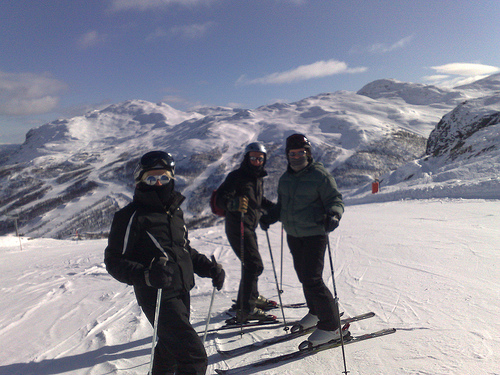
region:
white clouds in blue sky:
[22, 5, 67, 50]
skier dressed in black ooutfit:
[104, 146, 206, 348]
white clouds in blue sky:
[58, 15, 112, 47]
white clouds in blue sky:
[95, 43, 192, 84]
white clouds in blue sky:
[175, 21, 263, 82]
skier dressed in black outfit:
[205, 136, 275, 311]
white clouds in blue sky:
[251, 22, 329, 69]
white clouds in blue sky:
[345, 19, 412, 63]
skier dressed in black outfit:
[270, 132, 358, 317]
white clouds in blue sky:
[380, 29, 432, 66]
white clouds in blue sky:
[39, 43, 89, 81]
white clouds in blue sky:
[99, 23, 176, 55]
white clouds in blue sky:
[227, 17, 287, 42]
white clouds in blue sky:
[290, 45, 344, 85]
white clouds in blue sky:
[353, 28, 398, 53]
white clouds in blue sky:
[279, 38, 323, 66]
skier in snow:
[273, 128, 358, 335]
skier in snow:
[206, 144, 283, 301]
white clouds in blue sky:
[69, 49, 106, 66]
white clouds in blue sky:
[22, 63, 64, 101]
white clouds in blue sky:
[131, 30, 211, 94]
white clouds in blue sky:
[255, 40, 315, 89]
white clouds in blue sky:
[317, 7, 389, 45]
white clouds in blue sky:
[396, 20, 437, 48]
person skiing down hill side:
[270, 126, 360, 331]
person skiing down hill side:
[225, 130, 278, 312]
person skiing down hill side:
[112, 144, 221, 355]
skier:
[80, 148, 201, 366]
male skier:
[207, 138, 279, 305]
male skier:
[274, 132, 361, 370]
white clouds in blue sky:
[72, 59, 116, 93]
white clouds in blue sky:
[132, 11, 189, 75]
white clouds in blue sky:
[197, 11, 244, 69]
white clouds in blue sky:
[285, 35, 333, 76]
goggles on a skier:
[141, 171, 178, 184]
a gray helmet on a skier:
[243, 140, 271, 170]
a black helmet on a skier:
[284, 131, 312, 147]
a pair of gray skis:
[222, 307, 396, 373]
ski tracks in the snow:
[0, 288, 130, 357]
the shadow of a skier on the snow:
[0, 306, 224, 373]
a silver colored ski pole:
[142, 277, 164, 374]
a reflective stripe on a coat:
[121, 207, 136, 263]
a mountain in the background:
[1, 69, 497, 240]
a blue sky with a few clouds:
[2, 0, 497, 144]